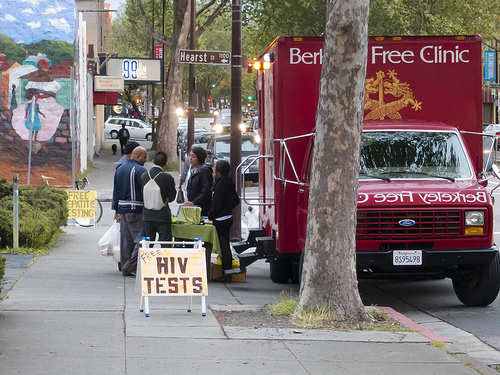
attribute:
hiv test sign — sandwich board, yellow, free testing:
[136, 240, 211, 302]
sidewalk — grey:
[1, 145, 495, 375]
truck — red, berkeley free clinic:
[252, 27, 500, 307]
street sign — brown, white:
[176, 50, 235, 66]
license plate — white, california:
[391, 247, 424, 267]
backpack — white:
[145, 170, 166, 211]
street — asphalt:
[368, 275, 499, 346]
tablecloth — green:
[170, 218, 220, 256]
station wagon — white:
[100, 113, 157, 140]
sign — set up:
[62, 185, 99, 224]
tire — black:
[452, 248, 500, 304]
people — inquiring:
[109, 138, 176, 276]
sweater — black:
[141, 165, 175, 223]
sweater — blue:
[111, 158, 150, 209]